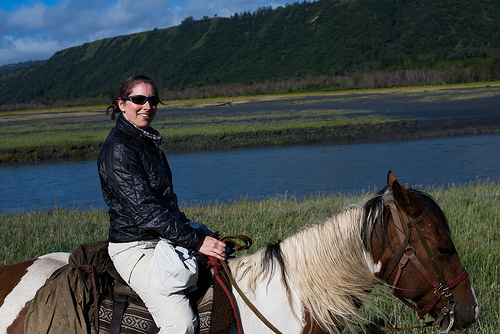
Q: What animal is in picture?
A: A horse.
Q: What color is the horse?
A: Brown and white.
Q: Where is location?
A: By a pond.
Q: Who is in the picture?
A: A woman.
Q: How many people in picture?
A: One.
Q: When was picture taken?
A: During daylight.